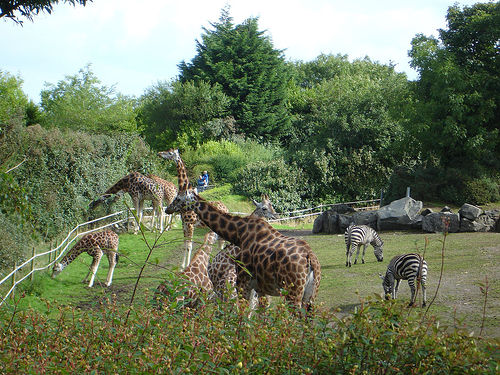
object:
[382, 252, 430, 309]
zebra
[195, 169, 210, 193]
man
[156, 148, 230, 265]
giraffe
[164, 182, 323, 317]
giraffe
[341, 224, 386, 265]
zebra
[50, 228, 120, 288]
giraffe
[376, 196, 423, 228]
rock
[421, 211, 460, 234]
rock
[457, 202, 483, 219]
rock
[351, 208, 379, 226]
rock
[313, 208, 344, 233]
rock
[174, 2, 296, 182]
trees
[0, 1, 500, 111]
sky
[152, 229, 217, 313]
giraffe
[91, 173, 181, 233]
giraffe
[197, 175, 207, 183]
shirt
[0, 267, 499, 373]
grass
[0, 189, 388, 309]
fence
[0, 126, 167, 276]
shrubs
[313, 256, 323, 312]
tail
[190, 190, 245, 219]
mane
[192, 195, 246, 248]
neck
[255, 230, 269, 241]
spot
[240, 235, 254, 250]
spot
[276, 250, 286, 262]
spot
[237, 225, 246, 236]
spot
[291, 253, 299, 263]
spot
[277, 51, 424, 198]
bush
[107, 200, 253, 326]
tree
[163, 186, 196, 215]
face